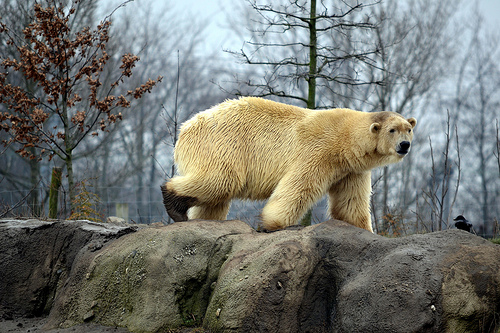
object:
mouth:
[397, 150, 408, 154]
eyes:
[390, 129, 412, 133]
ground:
[0, 210, 500, 243]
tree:
[424, 0, 496, 231]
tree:
[106, 0, 221, 225]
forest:
[0, 0, 499, 235]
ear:
[369, 123, 380, 133]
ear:
[408, 117, 418, 128]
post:
[49, 167, 63, 219]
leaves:
[0, 3, 167, 163]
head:
[369, 111, 418, 159]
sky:
[1, 1, 497, 224]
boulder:
[0, 219, 495, 332]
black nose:
[400, 141, 411, 150]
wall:
[109, 238, 303, 329]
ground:
[4, 321, 54, 333]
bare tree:
[207, 0, 419, 111]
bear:
[159, 96, 417, 235]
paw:
[173, 218, 187, 223]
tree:
[0, 1, 163, 219]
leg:
[173, 140, 246, 209]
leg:
[265, 161, 344, 208]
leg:
[325, 172, 373, 224]